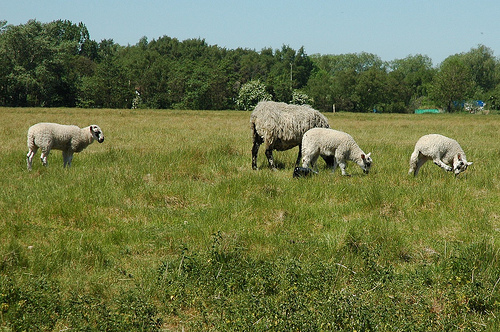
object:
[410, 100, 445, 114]
fence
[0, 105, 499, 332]
grass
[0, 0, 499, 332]
pasture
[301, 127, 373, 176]
lamb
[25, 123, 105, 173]
lamb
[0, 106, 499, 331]
field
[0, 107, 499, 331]
ground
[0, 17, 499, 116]
trees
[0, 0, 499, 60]
skies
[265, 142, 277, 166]
leg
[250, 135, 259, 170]
leg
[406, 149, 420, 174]
leg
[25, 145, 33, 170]
leg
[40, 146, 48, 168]
leg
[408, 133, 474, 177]
lamb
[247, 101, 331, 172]
lambs